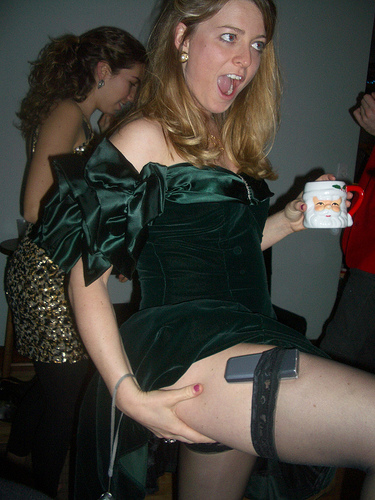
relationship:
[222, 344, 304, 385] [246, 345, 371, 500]
telephone strapped to a stocking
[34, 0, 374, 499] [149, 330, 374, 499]
woman has leg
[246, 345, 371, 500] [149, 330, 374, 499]
stocking on leg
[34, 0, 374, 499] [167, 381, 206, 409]
woman has thumb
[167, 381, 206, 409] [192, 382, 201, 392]
thumb has nail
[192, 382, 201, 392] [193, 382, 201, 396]
nail has polish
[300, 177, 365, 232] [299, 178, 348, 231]
mug shaped like santa claus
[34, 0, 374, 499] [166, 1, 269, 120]
woman has face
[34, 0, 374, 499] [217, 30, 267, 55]
woman has eyes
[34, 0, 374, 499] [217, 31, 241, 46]
woman has eye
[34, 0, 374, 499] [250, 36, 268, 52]
woman has eyes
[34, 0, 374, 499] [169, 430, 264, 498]
woman has leg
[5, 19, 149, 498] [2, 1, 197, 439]
girl in background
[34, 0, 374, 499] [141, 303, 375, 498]
woman has right leg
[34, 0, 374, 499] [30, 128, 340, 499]
woman wears dress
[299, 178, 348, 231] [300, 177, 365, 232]
santa claus on mug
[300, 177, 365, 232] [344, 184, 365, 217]
mug has handle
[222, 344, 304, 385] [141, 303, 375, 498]
phone on right leg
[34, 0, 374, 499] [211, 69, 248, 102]
woman has mouth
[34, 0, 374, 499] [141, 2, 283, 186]
woman has hair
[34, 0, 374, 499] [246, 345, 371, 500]
woman wears stocking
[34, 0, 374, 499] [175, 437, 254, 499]
woman wears stocking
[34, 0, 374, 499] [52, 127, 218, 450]
woman has arm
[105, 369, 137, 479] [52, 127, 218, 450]
strap around arm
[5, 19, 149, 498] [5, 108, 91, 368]
girl wears dress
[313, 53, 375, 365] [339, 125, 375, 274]
man wears sweatshirt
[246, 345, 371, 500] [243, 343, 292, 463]
stocking has top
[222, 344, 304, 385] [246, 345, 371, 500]
telephone in stocking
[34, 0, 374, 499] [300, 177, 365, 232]
woman holding mug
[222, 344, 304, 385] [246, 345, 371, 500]
phone in top of stocking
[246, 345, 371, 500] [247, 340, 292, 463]
stocking has garter band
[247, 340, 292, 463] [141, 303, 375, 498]
garter band around right leg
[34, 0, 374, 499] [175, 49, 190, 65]
woman wears earring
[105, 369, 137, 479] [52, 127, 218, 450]
strap on arm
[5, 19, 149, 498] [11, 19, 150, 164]
girl has hair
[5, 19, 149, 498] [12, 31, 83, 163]
girl has pony tail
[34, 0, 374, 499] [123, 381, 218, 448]
woman has hand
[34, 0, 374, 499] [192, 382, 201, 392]
woman has nail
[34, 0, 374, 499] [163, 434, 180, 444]
woman wears ring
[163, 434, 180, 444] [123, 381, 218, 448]
ring on a hand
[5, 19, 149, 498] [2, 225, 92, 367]
girl wears skirt